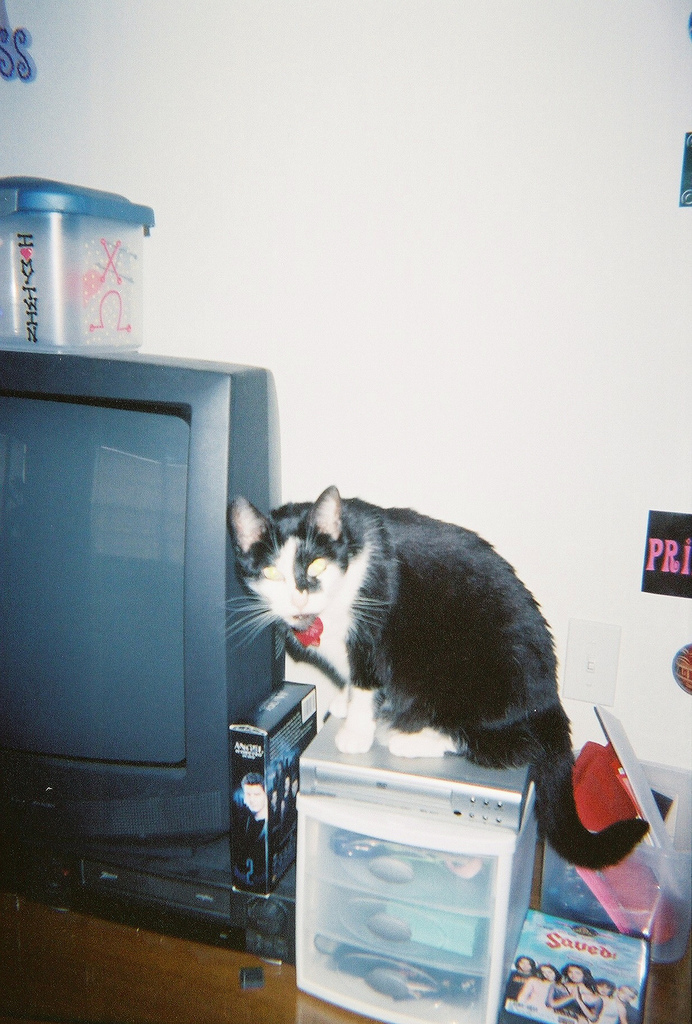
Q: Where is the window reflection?
A: On the tv.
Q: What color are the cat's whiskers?
A: White.